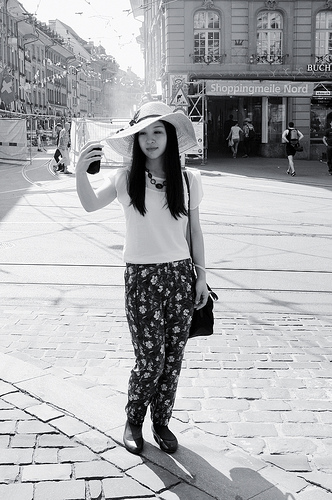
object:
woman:
[74, 101, 211, 455]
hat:
[105, 101, 197, 160]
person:
[227, 122, 242, 158]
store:
[139, 0, 327, 159]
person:
[242, 118, 256, 160]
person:
[281, 121, 304, 176]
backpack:
[291, 130, 298, 140]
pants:
[121, 258, 196, 430]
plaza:
[0, 156, 331, 499]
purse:
[184, 292, 215, 339]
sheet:
[68, 120, 132, 174]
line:
[0, 112, 137, 123]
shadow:
[129, 438, 295, 500]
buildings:
[0, 2, 143, 150]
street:
[0, 149, 53, 172]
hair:
[128, 123, 188, 221]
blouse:
[114, 165, 204, 266]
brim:
[106, 109, 196, 143]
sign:
[204, 82, 317, 98]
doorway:
[205, 96, 262, 162]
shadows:
[0, 261, 124, 288]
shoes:
[123, 422, 144, 453]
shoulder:
[179, 171, 194, 206]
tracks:
[213, 265, 331, 296]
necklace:
[146, 164, 168, 190]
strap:
[182, 171, 196, 281]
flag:
[45, 62, 69, 85]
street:
[0, 312, 332, 496]